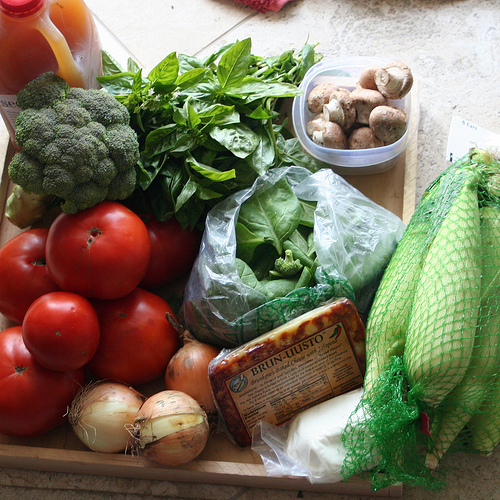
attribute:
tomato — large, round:
[57, 208, 167, 305]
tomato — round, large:
[10, 276, 104, 368]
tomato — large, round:
[5, 229, 75, 321]